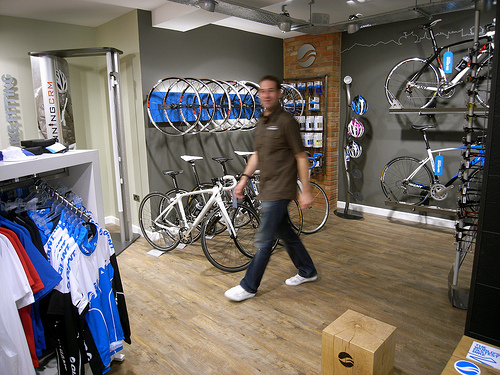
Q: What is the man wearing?
A: A shirt, jeans and sneakers.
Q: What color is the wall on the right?
A: Grey.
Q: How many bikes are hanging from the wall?
A: Two.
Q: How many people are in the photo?
A: One.